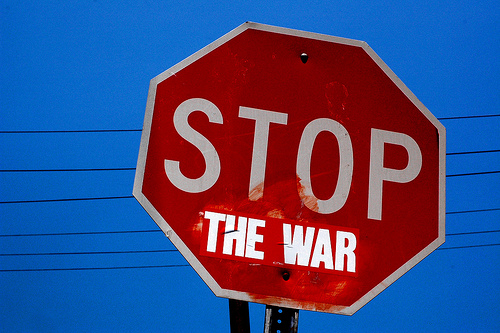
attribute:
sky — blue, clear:
[1, 0, 499, 333]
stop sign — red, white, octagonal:
[130, 17, 446, 314]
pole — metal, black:
[257, 305, 301, 332]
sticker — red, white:
[195, 203, 359, 278]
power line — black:
[0, 111, 499, 134]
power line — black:
[1, 149, 499, 176]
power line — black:
[0, 169, 499, 207]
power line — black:
[1, 206, 497, 236]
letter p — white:
[365, 122, 423, 220]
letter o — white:
[293, 117, 354, 214]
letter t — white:
[236, 102, 290, 204]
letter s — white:
[161, 95, 225, 192]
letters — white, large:
[204, 210, 355, 272]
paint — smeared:
[194, 166, 351, 311]